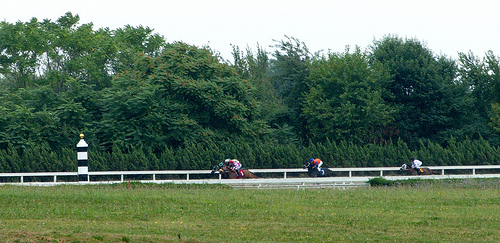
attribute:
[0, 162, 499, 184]
metal — white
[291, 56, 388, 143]
tree — green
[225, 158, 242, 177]
people — competing, trying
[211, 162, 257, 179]
horse — runing, running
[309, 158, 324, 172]
people — competing, trying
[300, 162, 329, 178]
horse — runing, running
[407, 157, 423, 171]
people — competing, trying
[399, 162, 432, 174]
horse — runing, running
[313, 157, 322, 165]
clothing — red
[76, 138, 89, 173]
post — white, black, stripe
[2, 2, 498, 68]
sky — cloudy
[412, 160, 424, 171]
clothing — white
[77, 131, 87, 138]
ball — golde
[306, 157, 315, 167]
helmet — blue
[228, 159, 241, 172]
outfit — red, white